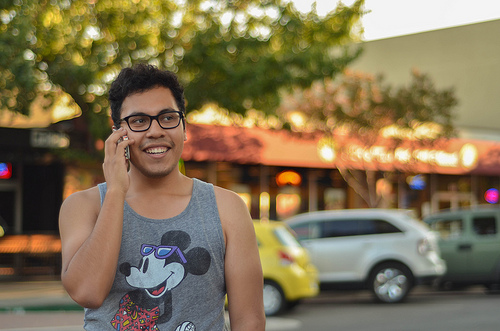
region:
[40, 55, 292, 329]
a latino man in a disney tank top talking on his cell phone outdoors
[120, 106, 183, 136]
nerdy eyeglasses the man is wearing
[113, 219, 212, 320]
Mickey Mouse on the man's shirt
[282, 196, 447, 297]
a white station-wagon type car in the background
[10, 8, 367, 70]
a blurred tree in the background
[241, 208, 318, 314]
the back of a bright yellow car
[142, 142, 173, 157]
the man's straight teeth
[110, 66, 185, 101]
the man's messy dark brown hair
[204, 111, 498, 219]
a strip mall of businesses in the background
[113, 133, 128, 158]
a cell phone the man is holding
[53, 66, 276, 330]
smiling black haired man listening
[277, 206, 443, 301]
large white new suv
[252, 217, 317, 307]
back of a yellow hatchback car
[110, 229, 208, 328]
mickey mouse logo with purple sunglasses on shirt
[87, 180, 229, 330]
grey tank top with logo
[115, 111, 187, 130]
black plastic hipster glasses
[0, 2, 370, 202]
large leafy green tree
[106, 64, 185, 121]
short fluffy black hair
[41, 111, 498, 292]
long one story shop in the distance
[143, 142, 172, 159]
big white teeth smile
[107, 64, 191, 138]
He wears black framed eyeglasses.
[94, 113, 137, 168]
He is talking on the cellphone.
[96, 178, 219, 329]
Mickey Mouse is on the tank top.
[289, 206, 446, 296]
The white SUV is parked.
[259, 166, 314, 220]
Neon lights the store window.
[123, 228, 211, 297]
Mickey has sunglasses on his head.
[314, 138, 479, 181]
Bright lights are on the roof.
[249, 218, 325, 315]
The yellow car is next to the SUV.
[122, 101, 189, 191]
The man has a nice smile.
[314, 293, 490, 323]
The street is paved.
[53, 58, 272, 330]
man on cell phone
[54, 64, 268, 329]
man wearing a tank top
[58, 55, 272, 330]
man with a mickey mouse shirt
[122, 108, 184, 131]
black eyeglasses on man's head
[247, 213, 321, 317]
yellow car in background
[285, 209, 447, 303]
white car in background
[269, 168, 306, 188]
neon sign in background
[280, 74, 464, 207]
tree in background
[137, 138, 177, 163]
man is smiling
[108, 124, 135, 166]
cellphone up to ear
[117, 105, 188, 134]
black eye glasses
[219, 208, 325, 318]
yellow car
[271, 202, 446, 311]
white car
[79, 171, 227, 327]
grey t-shirt with Mickey Mouse design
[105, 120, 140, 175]
cell phone that is in use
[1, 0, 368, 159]
large green tree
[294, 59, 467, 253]
Small tree by the sidewalk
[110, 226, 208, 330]
Mickey Mouse design with blue sunglasses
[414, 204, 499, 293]
Grey truck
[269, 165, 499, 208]
Colorful neon restaurant signs